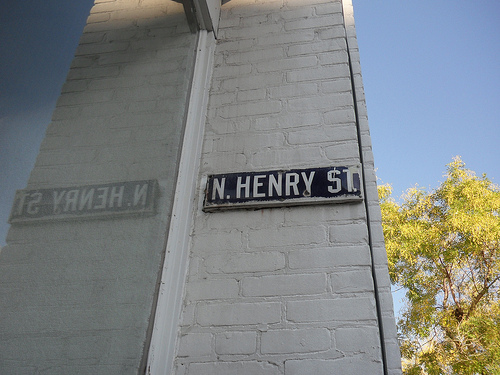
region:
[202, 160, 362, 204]
Black sign on building.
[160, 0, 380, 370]
Gray bricks on the building.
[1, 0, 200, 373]
Glass on the building.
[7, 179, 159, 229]
Reflection in the glass.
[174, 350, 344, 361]
Mortar between the bricks.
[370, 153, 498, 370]
Tree in the back ground.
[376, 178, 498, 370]
Green leaves on the tree.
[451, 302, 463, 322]
Brown nest in the tree.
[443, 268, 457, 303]
Brown tree branch.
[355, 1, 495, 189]
Blue sky in the background.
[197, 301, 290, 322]
White brick on a building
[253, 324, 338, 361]
White brick on a building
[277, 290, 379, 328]
White brick on a building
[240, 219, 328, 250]
White brick on a building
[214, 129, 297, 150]
White brick on a building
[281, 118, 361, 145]
White brick on a building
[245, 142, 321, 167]
White brick on a building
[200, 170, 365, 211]
White and black sign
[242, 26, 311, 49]
White brick on a building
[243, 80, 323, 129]
White brick on a building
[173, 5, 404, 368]
White column made of brick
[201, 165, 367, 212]
Old wooden sign on brick column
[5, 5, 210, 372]
Clear glass window on building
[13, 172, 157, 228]
Reflection of street sign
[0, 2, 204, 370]
Reflection of brick column in window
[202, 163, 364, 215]
Street sign with N. Henry St written on it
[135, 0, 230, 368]
White wooden window frame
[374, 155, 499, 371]
Tree with full leaf coverage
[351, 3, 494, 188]
Cloudless summer sky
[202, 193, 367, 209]
Faded paint on street sign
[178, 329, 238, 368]
White painted brick on building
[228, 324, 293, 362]
White painted brick on building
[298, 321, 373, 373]
White painted brick on building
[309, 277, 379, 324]
White painted brick on building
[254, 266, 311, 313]
White painted brick on building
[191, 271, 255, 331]
White painted brick on building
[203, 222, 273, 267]
White painted brick on building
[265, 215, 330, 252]
White painted brick on building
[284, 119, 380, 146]
White painted brick on building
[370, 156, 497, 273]
Large green tree top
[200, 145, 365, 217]
a sign on a wall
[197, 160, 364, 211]
sign is black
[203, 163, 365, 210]
sign has white letters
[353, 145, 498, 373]
a tree on side a buiding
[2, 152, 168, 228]
a sign reflected on a window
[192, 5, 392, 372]
wall of building is color gray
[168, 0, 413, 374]
wall of building is made of bricks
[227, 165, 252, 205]
letter H on sign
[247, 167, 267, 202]
letter E on sign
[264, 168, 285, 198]
letter N on sign